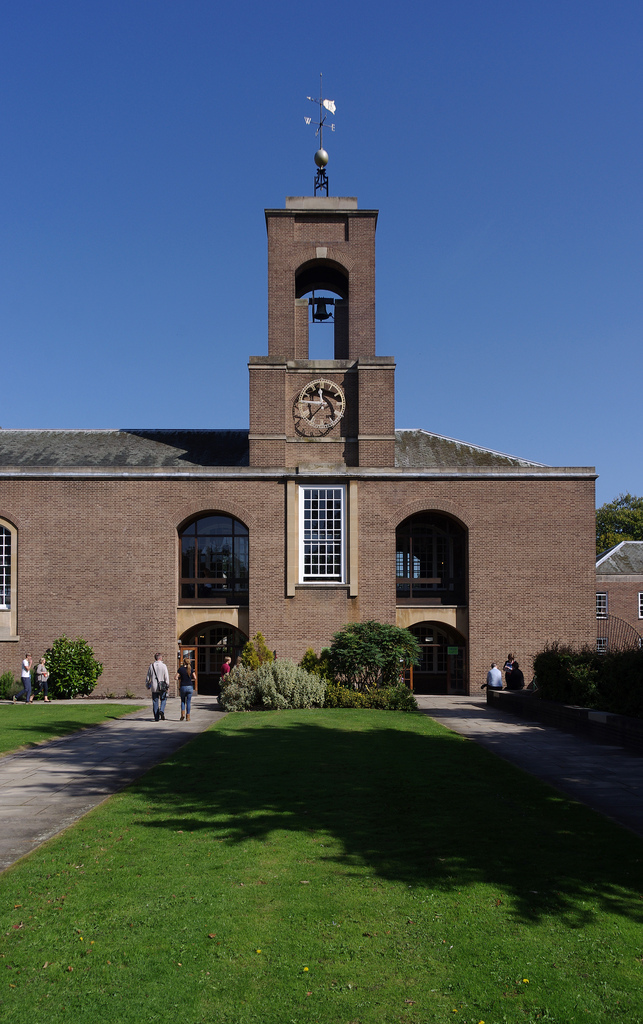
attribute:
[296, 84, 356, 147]
vane — tall weather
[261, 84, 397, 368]
belfry — arched 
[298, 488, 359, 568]
window — tall rectangular 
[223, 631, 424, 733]
tree — large shade , dark shadow  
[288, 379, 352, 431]
clock — cream colored , building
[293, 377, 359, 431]
clock — gold 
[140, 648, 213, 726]
people — walking 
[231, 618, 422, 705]
bushes — set  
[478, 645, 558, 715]
people — group 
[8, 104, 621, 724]
building —  large brick 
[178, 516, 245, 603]
window — arched glass 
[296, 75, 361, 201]
weathervane — silver 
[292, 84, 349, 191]
weathervane — building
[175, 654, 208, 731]
woman — black shirt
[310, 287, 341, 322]
bell — tower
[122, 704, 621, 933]
grass — shadow 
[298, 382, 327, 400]
hands — white 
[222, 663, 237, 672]
shirt — red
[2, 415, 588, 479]
roof — gray 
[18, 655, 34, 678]
shirt — white 